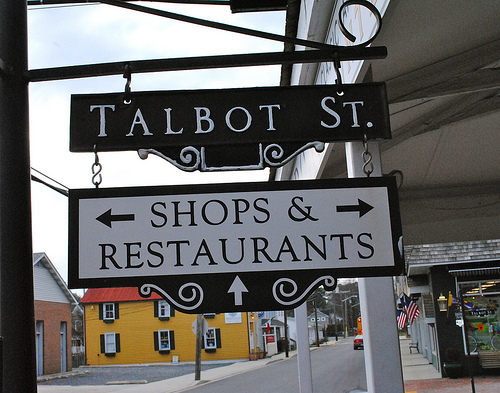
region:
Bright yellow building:
[74, 271, 279, 380]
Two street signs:
[54, 75, 415, 342]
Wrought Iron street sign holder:
[11, 14, 400, 126]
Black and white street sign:
[55, 163, 419, 335]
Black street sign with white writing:
[57, 51, 402, 179]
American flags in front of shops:
[384, 296, 425, 343]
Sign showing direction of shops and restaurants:
[69, 164, 404, 389]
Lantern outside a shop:
[428, 290, 454, 320]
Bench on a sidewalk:
[368, 291, 467, 384]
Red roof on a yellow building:
[75, 266, 205, 328]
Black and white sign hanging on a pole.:
[2, 1, 435, 353]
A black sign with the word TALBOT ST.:
[57, 80, 403, 160]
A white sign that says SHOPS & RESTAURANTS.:
[57, 179, 419, 283]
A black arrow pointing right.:
[327, 191, 385, 223]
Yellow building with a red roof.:
[78, 287, 270, 372]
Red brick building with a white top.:
[33, 242, 78, 384]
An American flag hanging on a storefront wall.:
[396, 290, 426, 327]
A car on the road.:
[343, 329, 366, 352]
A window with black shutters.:
[142, 326, 186, 356]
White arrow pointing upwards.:
[217, 274, 254, 311]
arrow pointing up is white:
[218, 270, 255, 312]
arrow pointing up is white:
[207, 260, 262, 318]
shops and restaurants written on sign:
[55, 182, 416, 288]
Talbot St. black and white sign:
[76, 60, 391, 162]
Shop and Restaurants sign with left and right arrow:
[47, 183, 441, 280]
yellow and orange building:
[85, 288, 260, 368]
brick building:
[29, 231, 79, 378]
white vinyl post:
[339, 284, 457, 388]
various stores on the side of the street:
[408, 247, 498, 375]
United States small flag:
[388, 293, 420, 345]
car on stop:
[334, 326, 368, 353]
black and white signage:
[21, 21, 411, 358]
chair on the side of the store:
[403, 334, 424, 353]